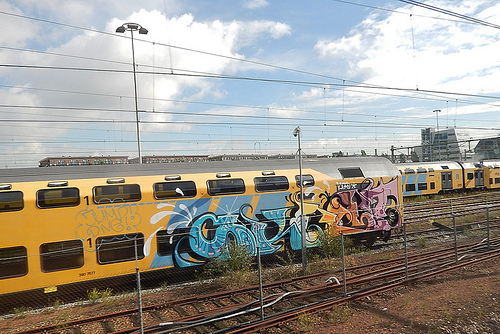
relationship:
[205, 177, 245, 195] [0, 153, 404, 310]
window on train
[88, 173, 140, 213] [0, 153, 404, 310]
window on side of train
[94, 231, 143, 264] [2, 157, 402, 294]
lower window on train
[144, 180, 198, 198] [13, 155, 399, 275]
window on train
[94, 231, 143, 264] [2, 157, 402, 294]
lower window in train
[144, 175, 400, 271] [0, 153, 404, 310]
graffiti spray painted on train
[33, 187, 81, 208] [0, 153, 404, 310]
window built into train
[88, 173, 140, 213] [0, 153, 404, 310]
window built into train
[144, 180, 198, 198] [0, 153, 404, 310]
window built into train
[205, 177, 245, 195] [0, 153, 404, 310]
window built into train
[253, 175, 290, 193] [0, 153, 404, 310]
long window built into train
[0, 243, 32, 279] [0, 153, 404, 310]
lower window built into train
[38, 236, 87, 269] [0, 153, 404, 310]
lower window built into train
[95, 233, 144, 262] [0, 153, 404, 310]
lower window built into train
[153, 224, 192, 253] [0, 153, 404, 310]
lower window built into train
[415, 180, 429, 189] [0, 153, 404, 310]
lower window built into train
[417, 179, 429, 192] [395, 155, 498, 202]
window built into train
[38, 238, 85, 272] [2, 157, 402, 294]
lower window built into train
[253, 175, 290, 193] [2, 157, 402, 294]
long window built into train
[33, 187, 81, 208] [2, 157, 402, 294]
window built into train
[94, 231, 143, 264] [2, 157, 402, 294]
lower window built into train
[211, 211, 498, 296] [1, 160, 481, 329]
fence bordering rail yard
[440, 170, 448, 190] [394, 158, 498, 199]
door leading to train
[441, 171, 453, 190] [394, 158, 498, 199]
door leading to train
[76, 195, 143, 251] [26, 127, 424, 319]
graffiti spray painted on train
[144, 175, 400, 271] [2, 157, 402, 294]
graffiti spray painted on train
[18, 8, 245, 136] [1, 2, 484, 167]
cloud hanging in sky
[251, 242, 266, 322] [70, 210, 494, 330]
post supporting fence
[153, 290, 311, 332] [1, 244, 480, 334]
line lying on top of rail yard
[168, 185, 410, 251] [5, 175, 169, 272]
graffiti on side of train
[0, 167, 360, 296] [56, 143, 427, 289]
paint on train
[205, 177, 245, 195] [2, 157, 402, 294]
window on train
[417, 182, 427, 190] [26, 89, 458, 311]
lower window on train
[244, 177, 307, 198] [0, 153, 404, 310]
long window on train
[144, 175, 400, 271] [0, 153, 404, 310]
graffiti on side of train